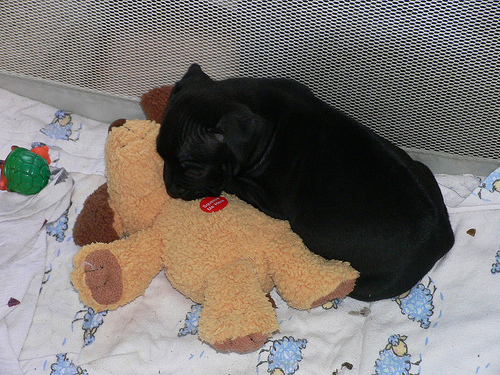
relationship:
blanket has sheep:
[1, 87, 499, 373] [375, 334, 420, 374]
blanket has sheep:
[1, 87, 499, 373] [40, 110, 82, 140]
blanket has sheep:
[1, 87, 499, 373] [71, 309, 106, 345]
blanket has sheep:
[1, 87, 499, 373] [392, 276, 439, 328]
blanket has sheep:
[1, 87, 499, 373] [50, 352, 84, 374]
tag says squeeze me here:
[199, 196, 228, 211] [200, 196, 224, 209]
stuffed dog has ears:
[72, 85, 360, 353] [76, 183, 119, 243]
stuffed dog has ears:
[72, 85, 360, 353] [141, 84, 169, 123]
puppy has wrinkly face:
[157, 64, 454, 300] [159, 115, 219, 197]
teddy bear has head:
[72, 85, 360, 353] [106, 119, 165, 233]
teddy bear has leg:
[72, 85, 360, 353] [202, 276, 270, 353]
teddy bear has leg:
[72, 85, 360, 353] [278, 252, 358, 309]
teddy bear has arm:
[72, 85, 360, 353] [69, 229, 160, 312]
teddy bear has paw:
[72, 85, 360, 353] [85, 250, 124, 305]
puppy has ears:
[72, 85, 360, 353] [76, 183, 119, 243]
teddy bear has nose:
[72, 85, 360, 353] [109, 119, 124, 130]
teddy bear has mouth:
[72, 85, 360, 353] [115, 127, 157, 149]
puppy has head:
[157, 64, 454, 300] [156, 79, 236, 201]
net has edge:
[1, 0, 499, 179] [1, 72, 499, 177]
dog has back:
[157, 64, 454, 300] [238, 87, 436, 242]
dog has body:
[157, 64, 454, 300] [233, 78, 455, 300]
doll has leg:
[72, 85, 360, 353] [202, 276, 270, 353]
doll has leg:
[72, 85, 360, 353] [278, 252, 358, 309]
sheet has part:
[1, 87, 499, 373] [445, 310, 498, 374]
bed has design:
[1, 87, 499, 373] [375, 334, 420, 374]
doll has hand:
[72, 85, 360, 353] [71, 243, 139, 310]